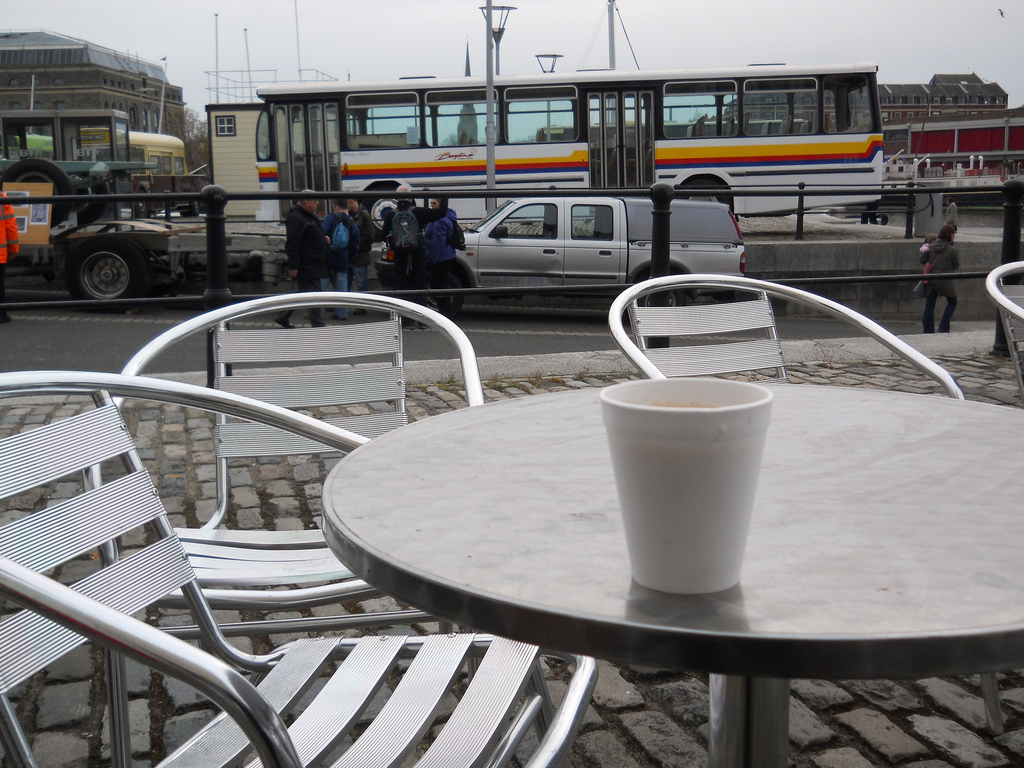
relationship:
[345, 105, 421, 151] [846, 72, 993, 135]
window on building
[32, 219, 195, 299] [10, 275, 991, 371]
car on street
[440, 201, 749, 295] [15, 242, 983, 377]
truck on street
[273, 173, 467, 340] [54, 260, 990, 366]
people standing in street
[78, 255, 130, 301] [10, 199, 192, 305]
tire on truck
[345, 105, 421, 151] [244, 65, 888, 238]
window on bus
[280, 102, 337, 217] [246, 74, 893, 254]
door on bus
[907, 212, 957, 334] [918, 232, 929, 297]
person carrying child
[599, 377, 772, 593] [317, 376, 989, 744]
cup on table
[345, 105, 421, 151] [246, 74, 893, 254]
window on bus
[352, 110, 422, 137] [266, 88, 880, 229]
window on bus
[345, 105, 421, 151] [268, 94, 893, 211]
window on bus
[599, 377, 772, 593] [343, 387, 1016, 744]
cup on table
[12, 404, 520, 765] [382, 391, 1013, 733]
chair next to table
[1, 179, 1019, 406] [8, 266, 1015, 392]
fence alongside road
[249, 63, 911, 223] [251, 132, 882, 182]
bus with stripe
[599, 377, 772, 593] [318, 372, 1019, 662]
cup sitting on table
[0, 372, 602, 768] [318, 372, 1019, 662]
chair at table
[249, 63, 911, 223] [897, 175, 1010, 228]
bus parked in lot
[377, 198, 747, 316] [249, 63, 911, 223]
truck parked  by bus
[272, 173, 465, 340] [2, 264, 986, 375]
people standing in lot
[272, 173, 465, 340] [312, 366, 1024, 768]
people behind table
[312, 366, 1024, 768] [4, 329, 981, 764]
table on sidewalk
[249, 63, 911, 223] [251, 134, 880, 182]
bus with lines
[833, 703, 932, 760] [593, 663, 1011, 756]
brick on sidewalk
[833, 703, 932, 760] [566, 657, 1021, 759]
brick on sidewalk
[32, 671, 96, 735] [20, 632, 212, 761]
brick on sidewalk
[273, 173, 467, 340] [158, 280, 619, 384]
people on street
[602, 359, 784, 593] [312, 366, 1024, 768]
cup on table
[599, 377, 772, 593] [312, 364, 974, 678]
cup on a table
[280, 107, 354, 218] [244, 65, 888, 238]
door of bus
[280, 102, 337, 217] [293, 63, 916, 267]
door of a bus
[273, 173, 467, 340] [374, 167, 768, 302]
people gathered next to a car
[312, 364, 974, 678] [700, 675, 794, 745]
table on a leg